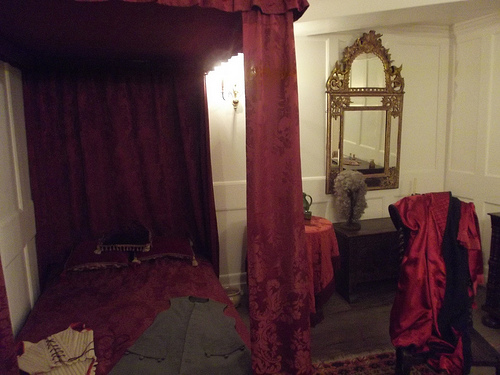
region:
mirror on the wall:
[319, 37, 424, 189]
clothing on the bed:
[151, 280, 253, 372]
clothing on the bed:
[24, 313, 91, 370]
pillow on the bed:
[94, 224, 161, 257]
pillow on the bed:
[156, 223, 199, 264]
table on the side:
[251, 217, 343, 320]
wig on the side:
[327, 168, 378, 230]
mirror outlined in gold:
[333, 73, 413, 193]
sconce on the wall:
[211, 73, 243, 118]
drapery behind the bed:
[62, 73, 202, 230]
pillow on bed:
[73, 224, 201, 270]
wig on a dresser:
[323, 157, 376, 229]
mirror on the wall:
[325, 35, 410, 195]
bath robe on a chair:
[373, 175, 475, 361]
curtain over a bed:
[228, 13, 362, 360]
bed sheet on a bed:
[59, 250, 151, 373]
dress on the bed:
[126, 283, 226, 373]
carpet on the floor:
[346, 282, 414, 364]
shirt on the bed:
[15, 323, 101, 371]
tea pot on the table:
[296, 183, 310, 218]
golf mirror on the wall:
[323, 28, 421, 192]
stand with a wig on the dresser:
[326, 165, 371, 231]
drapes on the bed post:
[228, 20, 305, 372]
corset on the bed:
[18, 325, 88, 365]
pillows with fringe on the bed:
[95, 220, 166, 275]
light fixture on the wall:
[213, 69, 239, 118]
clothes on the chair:
[383, 197, 471, 357]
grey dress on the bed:
[134, 287, 251, 372]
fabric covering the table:
[313, 210, 347, 297]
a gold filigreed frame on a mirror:
[322, 31, 403, 191]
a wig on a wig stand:
[334, 170, 367, 225]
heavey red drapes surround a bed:
[8, 0, 301, 368]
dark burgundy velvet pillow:
[98, 222, 154, 254]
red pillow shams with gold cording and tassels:
[63, 226, 203, 276]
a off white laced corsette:
[13, 319, 95, 374]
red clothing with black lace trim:
[389, 194, 481, 373]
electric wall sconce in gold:
[213, 67, 250, 123]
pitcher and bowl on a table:
[301, 183, 314, 222]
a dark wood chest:
[341, 221, 430, 311]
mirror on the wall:
[316, 25, 415, 186]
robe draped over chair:
[372, 188, 497, 374]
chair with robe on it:
[383, 190, 475, 365]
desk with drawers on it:
[328, 204, 418, 303]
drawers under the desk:
[363, 240, 413, 273]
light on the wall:
[219, 69, 266, 121]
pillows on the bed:
[71, 217, 193, 270]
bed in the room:
[51, 234, 251, 372]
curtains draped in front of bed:
[234, 54, 324, 373]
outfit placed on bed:
[115, 283, 260, 373]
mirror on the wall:
[324, 24, 404, 200]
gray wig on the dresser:
[317, 163, 381, 228]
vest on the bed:
[6, 317, 94, 370]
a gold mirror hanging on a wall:
[322, 35, 409, 192]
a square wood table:
[340, 219, 403, 307]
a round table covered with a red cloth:
[303, 210, 334, 299]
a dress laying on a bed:
[127, 294, 237, 373]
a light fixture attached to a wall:
[216, 67, 248, 112]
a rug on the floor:
[315, 335, 392, 373]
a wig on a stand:
[331, 166, 370, 233]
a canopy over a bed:
[70, 0, 321, 323]